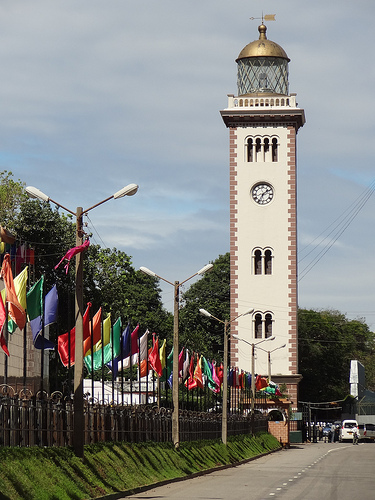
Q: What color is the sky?
A: Clouds.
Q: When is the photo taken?
A: Daytime.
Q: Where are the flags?
A: On the fence.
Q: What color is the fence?
A: Black.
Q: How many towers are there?
A: One.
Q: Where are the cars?
A: On the road.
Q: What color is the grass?
A: Green.